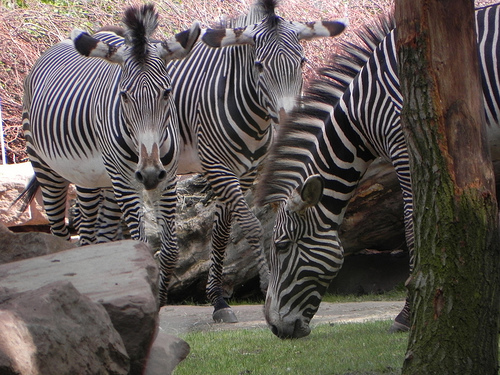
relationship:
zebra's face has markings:
[252, 27, 305, 117] [274, 43, 288, 73]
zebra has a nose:
[33, 5, 174, 232] [132, 155, 168, 190]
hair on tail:
[228, 73, 234, 99] [13, 182, 39, 216]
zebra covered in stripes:
[33, 5, 174, 232] [47, 75, 92, 128]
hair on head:
[248, 4, 277, 19] [72, 13, 204, 126]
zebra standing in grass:
[33, 5, 174, 232] [255, 350, 357, 374]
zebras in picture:
[18, 7, 442, 362] [4, 6, 499, 352]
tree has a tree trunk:
[396, 22, 470, 104] [390, 1, 499, 375]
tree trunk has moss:
[406, 13, 469, 43] [442, 196, 492, 259]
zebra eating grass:
[33, 5, 174, 232] [255, 350, 357, 374]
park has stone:
[18, 7, 442, 362] [179, 309, 206, 328]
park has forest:
[10, 19, 496, 204] [18, 6, 81, 35]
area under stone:
[155, 343, 191, 374] [179, 309, 206, 328]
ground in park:
[332, 303, 383, 319] [10, 19, 496, 204]